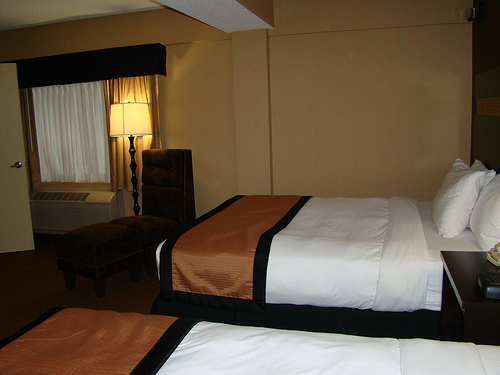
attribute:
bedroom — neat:
[2, 14, 494, 366]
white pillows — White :
[428, 157, 498, 252]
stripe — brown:
[159, 188, 313, 305]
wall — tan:
[6, 7, 481, 267]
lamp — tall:
[100, 76, 172, 257]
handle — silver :
[7, 152, 27, 177]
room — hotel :
[6, 2, 494, 371]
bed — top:
[154, 191, 484, 312]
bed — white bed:
[131, 131, 473, 318]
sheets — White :
[169, 191, 427, 302]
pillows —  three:
[428, 150, 498, 252]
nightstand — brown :
[435, 245, 499, 345]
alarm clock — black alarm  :
[476, 270, 499, 298]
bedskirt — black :
[152, 257, 444, 318]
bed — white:
[156, 189, 498, 318]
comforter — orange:
[158, 193, 428, 309]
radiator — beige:
[27, 187, 121, 234]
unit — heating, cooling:
[30, 188, 118, 230]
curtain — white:
[17, 80, 113, 180]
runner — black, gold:
[163, 179, 318, 258]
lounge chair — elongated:
[56, 149, 193, 295]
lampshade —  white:
[101, 95, 159, 142]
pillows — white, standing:
[432, 156, 498, 278]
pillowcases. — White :
[435, 154, 493, 247]